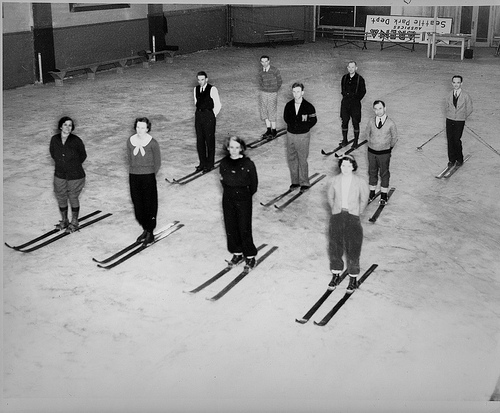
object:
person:
[255, 55, 282, 143]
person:
[325, 152, 369, 296]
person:
[218, 133, 258, 273]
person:
[125, 117, 160, 245]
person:
[440, 74, 472, 169]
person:
[281, 81, 317, 194]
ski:
[311, 263, 379, 333]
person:
[191, 71, 220, 174]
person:
[48, 116, 86, 233]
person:
[365, 99, 397, 204]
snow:
[0, 52, 499, 413]